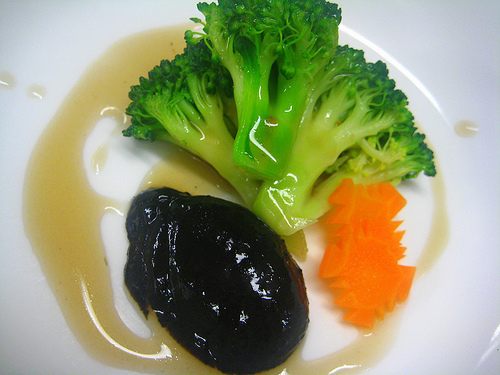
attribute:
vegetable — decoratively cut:
[320, 170, 410, 334]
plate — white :
[0, 0, 495, 374]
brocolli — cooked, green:
[132, 9, 429, 239]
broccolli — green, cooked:
[253, 45, 435, 237]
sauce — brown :
[22, 22, 447, 373]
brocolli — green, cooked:
[117, 6, 439, 235]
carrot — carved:
[323, 184, 417, 323]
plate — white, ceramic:
[21, 30, 498, 352]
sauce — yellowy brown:
[5, 26, 330, 368]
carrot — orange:
[316, 176, 418, 331]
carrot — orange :
[305, 167, 442, 333]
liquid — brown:
[26, 37, 447, 371]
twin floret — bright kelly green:
[197, 5, 360, 185]